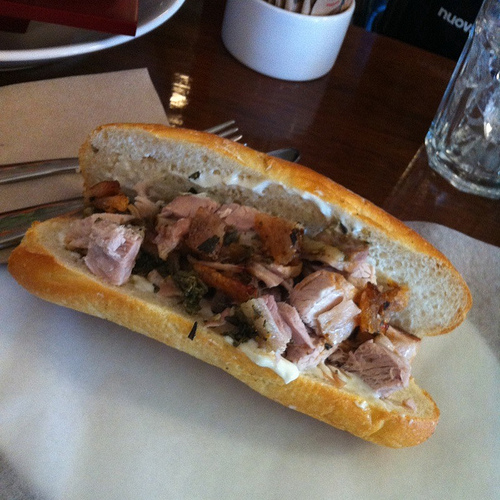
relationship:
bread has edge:
[6, 117, 481, 453] [10, 271, 394, 451]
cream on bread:
[102, 158, 362, 237] [6, 117, 481, 453]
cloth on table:
[0, 62, 186, 224] [5, 3, 498, 498]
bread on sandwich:
[6, 117, 481, 453] [3, 117, 477, 459]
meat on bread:
[70, 195, 418, 396] [6, 117, 481, 453]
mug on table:
[419, 1, 500, 199] [5, 3, 498, 498]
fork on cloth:
[2, 117, 251, 190] [0, 62, 186, 224]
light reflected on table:
[165, 69, 195, 129] [5, 3, 498, 498]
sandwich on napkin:
[3, 117, 477, 459] [4, 214, 498, 498]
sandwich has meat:
[3, 117, 477, 459] [70, 195, 418, 396]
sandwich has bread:
[3, 117, 477, 459] [6, 117, 481, 453]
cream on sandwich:
[102, 158, 362, 237] [3, 117, 477, 459]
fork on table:
[2, 117, 251, 190] [5, 3, 498, 498]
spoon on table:
[0, 145, 302, 240] [5, 3, 498, 498]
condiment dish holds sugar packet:
[217, 1, 362, 85] [311, 2, 348, 21]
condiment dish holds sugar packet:
[217, 1, 362, 85] [301, 0, 313, 18]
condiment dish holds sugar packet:
[217, 1, 362, 85] [287, 0, 302, 16]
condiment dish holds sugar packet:
[217, 1, 362, 85] [273, 1, 284, 9]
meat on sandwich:
[70, 195, 418, 396] [3, 117, 477, 459]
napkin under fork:
[0, 62, 186, 224] [2, 117, 251, 190]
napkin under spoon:
[0, 62, 186, 224] [0, 145, 302, 240]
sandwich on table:
[3, 117, 477, 459] [5, 3, 498, 498]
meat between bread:
[70, 195, 418, 396] [6, 117, 481, 453]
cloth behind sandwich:
[0, 62, 186, 224] [3, 117, 477, 459]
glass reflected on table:
[419, 1, 500, 199] [5, 3, 498, 498]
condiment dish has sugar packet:
[217, 1, 362, 85] [311, 2, 348, 21]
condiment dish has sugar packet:
[217, 1, 362, 85] [301, 0, 313, 18]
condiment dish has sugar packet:
[217, 1, 362, 85] [287, 0, 302, 16]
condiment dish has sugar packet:
[217, 1, 362, 85] [273, 1, 284, 9]